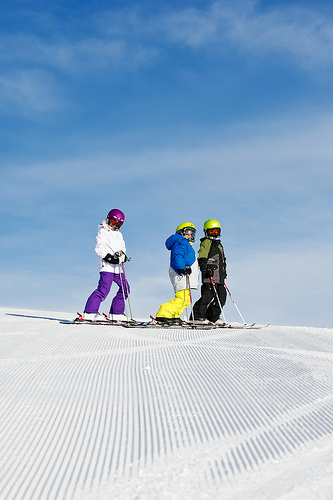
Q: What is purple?
A: Pants.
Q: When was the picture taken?
A: Daytime.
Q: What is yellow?
A: Pants.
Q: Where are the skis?
A: On the ground.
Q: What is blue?
A: Sky.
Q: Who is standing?
A: Skiers.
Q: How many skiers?
A: Three.